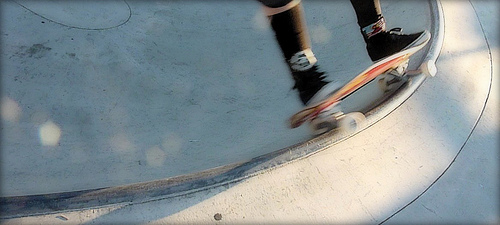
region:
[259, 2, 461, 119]
some legs on skateboard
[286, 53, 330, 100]
a white and black sneaker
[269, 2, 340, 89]
a brown sock and black shoe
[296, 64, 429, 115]
a red and white skateboard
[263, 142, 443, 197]
the edge of a skate ramp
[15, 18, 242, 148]
a blue covered pool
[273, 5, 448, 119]
a skateboarder facing up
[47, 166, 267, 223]
shadow of skateboarder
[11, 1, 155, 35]
circular pattern in pool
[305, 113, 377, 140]
spinning skateboard wheel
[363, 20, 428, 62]
black shoe on a skateboard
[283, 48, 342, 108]
black and white shoe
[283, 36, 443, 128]
colorful skateboard with white wheels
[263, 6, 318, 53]
black sock pulled up to a persons calve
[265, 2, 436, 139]
person on a skateboard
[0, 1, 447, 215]
empty pool with a person skateboarding in it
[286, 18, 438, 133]
sneakers on a skateboard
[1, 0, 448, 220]
empty concrete pool with a person skateboarding in it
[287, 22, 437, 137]
black and white shoes riding a skateboard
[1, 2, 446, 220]
empty pool with someone skating around the rim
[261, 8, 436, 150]
two feet on a skateboard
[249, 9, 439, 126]
two feet in sneakers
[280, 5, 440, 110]
two feet in shoes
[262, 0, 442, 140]
two feet in brown socks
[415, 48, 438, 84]
wheel of a skateboard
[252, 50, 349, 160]
foot on a skateboard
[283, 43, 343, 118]
a foot in a sneaker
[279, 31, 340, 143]
a foot in a shoe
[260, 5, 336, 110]
a foot in a brown sock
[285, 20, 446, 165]
skateboard on a rail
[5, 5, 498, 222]
Exterior, close-up of legs.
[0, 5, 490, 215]
Depiction of year-round sport and facility for it.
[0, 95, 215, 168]
Floater lights from proximity of shot.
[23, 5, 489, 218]
Grey skating ramp.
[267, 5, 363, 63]
Brown socks, on skateboarder.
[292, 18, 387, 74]
Detail on socks.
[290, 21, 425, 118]
Red, white and yellow skateboard.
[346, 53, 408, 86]
Wave-like edge, on skateboard.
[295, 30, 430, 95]
Black Converse sneakers with white soles.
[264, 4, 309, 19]
Right shin, shows skin between pant leg and sock.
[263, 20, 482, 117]
the sneaker is black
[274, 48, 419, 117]
the sneaker is black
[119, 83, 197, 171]
the ramp is gray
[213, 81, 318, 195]
the ramp is gray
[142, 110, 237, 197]
the ramp is gray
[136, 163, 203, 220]
the ramp is gray